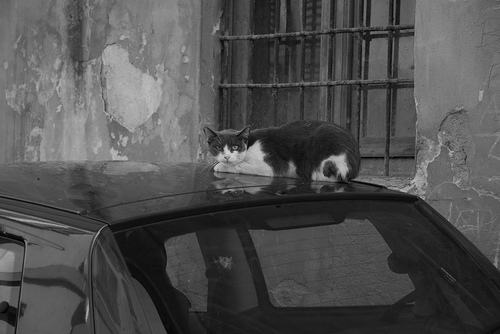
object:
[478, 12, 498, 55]
b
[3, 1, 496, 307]
wall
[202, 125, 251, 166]
head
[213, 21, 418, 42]
bars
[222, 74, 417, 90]
bars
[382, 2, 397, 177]
bars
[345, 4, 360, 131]
bars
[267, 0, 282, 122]
bars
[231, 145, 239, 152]
eyes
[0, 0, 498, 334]
building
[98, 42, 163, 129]
mark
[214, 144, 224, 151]
eyes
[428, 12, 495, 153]
wall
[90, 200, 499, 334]
windshield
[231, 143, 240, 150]
eye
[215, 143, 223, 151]
eye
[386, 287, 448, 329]
steering wheel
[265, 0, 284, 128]
bars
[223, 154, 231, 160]
nose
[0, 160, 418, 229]
roof top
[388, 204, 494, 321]
windshield wiper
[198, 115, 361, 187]
many wires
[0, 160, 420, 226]
roof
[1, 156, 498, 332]
black car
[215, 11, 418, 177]
house window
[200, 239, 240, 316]
seat belt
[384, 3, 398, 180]
pole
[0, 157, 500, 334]
car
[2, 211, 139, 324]
reflection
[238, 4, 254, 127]
bar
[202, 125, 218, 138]
pointy ears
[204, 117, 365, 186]
cat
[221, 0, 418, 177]
window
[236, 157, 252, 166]
whiskers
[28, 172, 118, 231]
paint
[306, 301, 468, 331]
dashboard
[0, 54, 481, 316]
camera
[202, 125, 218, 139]
ears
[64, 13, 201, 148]
wall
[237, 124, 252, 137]
ears